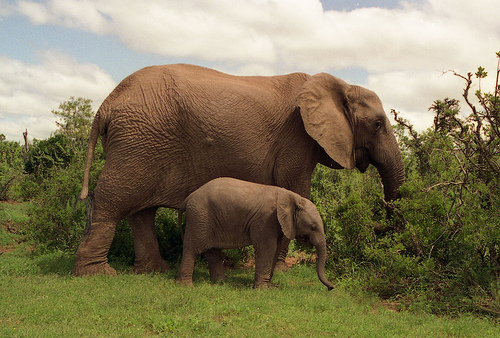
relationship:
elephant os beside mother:
[178, 174, 333, 295] [72, 63, 404, 275]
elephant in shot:
[178, 174, 333, 295] [4, 1, 498, 338]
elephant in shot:
[72, 63, 404, 275] [4, 1, 498, 338]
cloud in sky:
[21, 2, 500, 68] [0, 0, 497, 145]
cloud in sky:
[0, 54, 118, 142] [0, 0, 497, 145]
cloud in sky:
[367, 68, 499, 140] [0, 0, 497, 145]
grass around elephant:
[2, 196, 499, 338] [178, 174, 333, 295]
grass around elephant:
[2, 196, 499, 338] [72, 63, 404, 275]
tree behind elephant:
[19, 97, 110, 268] [72, 63, 404, 275]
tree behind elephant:
[305, 164, 384, 267] [72, 63, 404, 275]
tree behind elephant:
[410, 62, 497, 313] [72, 63, 404, 275]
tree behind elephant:
[19, 97, 110, 268] [178, 174, 333, 295]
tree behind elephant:
[305, 164, 384, 267] [178, 174, 333, 295]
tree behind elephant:
[410, 62, 497, 313] [178, 174, 333, 295]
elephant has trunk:
[178, 174, 333, 295] [317, 246, 333, 293]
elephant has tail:
[72, 63, 404, 275] [80, 101, 107, 200]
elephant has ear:
[178, 174, 333, 295] [276, 191, 295, 238]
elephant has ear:
[72, 63, 404, 275] [298, 73, 360, 168]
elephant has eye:
[178, 174, 333, 295] [309, 222, 320, 239]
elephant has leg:
[178, 174, 333, 295] [204, 247, 238, 282]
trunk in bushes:
[374, 138, 405, 217] [367, 137, 443, 270]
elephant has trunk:
[72, 63, 404, 275] [374, 138, 405, 217]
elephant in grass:
[178, 174, 333, 295] [2, 196, 499, 338]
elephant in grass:
[72, 63, 404, 275] [2, 196, 499, 338]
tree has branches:
[410, 62, 497, 313] [459, 67, 483, 158]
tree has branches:
[410, 62, 497, 313] [476, 86, 500, 146]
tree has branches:
[410, 62, 497, 313] [422, 173, 468, 193]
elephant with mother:
[178, 174, 333, 295] [72, 63, 404, 275]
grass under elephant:
[2, 196, 499, 338] [178, 174, 333, 295]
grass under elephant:
[2, 196, 499, 338] [72, 63, 404, 275]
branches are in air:
[459, 67, 483, 158] [389, 52, 495, 218]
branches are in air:
[476, 86, 500, 146] [389, 52, 495, 218]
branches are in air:
[422, 173, 468, 193] [389, 52, 495, 218]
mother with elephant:
[72, 63, 404, 275] [178, 174, 333, 295]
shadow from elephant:
[39, 253, 146, 277] [72, 63, 404, 275]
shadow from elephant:
[170, 266, 275, 283] [178, 174, 333, 295]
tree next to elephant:
[19, 97, 110, 268] [178, 174, 333, 295]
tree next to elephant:
[305, 164, 384, 267] [178, 174, 333, 295]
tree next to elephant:
[410, 62, 497, 313] [178, 174, 333, 295]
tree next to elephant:
[19, 97, 110, 268] [72, 63, 404, 275]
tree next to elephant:
[305, 164, 384, 267] [72, 63, 404, 275]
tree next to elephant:
[410, 62, 497, 313] [72, 63, 404, 275]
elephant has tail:
[178, 174, 333, 295] [176, 198, 188, 245]